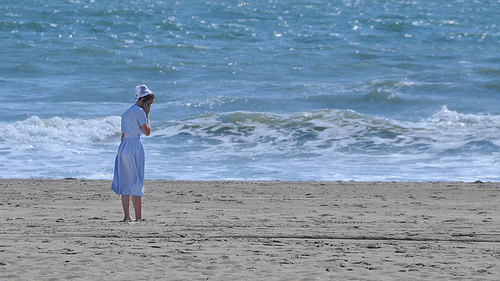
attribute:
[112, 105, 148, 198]
dress — blue, flowy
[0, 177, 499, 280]
beach — sandy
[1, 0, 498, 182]
ocean — blue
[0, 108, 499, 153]
wave — white, blue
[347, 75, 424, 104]
wave — turquoise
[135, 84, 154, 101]
hat — white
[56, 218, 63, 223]
sand — brown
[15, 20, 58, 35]
wave — blue, white